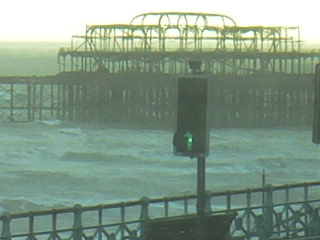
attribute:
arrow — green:
[180, 127, 197, 157]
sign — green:
[166, 67, 222, 162]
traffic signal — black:
[170, 59, 217, 230]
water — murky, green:
[0, 119, 196, 213]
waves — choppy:
[32, 127, 142, 193]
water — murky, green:
[14, 131, 164, 184]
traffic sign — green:
[174, 73, 208, 157]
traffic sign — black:
[172, 75, 211, 160]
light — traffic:
[162, 65, 213, 171]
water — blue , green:
[34, 130, 132, 206]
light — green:
[176, 129, 196, 153]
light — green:
[180, 128, 198, 158]